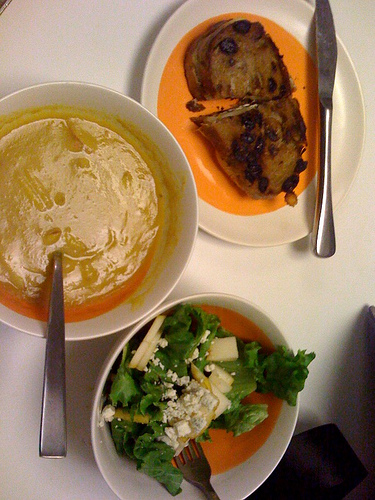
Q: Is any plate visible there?
A: Yes, there is a plate.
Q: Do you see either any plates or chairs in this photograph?
A: Yes, there is a plate.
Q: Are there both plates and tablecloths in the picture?
A: No, there is a plate but no tablecloths.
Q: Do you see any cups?
A: No, there are no cups.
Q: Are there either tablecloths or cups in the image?
A: No, there are no cups or tablecloths.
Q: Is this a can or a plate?
A: This is a plate.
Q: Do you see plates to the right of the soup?
A: Yes, there is a plate to the right of the soup.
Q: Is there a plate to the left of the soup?
A: No, the plate is to the right of the soup.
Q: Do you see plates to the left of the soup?
A: No, the plate is to the right of the soup.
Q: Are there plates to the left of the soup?
A: No, the plate is to the right of the soup.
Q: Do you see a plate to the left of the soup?
A: No, the plate is to the right of the soup.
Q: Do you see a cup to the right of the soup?
A: No, there is a plate to the right of the soup.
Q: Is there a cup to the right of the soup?
A: No, there is a plate to the right of the soup.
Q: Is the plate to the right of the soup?
A: Yes, the plate is to the right of the soup.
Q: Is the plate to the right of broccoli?
A: No, the plate is to the right of the soup.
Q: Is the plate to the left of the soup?
A: No, the plate is to the right of the soup.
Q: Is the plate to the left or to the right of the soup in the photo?
A: The plate is to the right of the soup.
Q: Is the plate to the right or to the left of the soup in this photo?
A: The plate is to the right of the soup.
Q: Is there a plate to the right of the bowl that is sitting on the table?
A: Yes, there is a plate to the right of the bowl.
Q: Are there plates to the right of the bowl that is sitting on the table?
A: Yes, there is a plate to the right of the bowl.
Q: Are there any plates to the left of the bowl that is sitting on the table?
A: No, the plate is to the right of the bowl.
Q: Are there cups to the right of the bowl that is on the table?
A: No, there is a plate to the right of the bowl.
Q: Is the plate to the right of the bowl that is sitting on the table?
A: Yes, the plate is to the right of the bowl.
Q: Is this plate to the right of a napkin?
A: No, the plate is to the right of the bowl.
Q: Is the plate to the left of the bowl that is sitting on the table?
A: No, the plate is to the right of the bowl.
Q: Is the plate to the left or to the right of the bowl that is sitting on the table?
A: The plate is to the right of the bowl.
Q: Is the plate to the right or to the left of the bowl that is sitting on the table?
A: The plate is to the right of the bowl.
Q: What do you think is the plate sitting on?
A: The plate is sitting on the table.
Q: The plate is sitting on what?
A: The plate is sitting on the table.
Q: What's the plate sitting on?
A: The plate is sitting on the table.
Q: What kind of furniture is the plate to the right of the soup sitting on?
A: The plate is sitting on the table.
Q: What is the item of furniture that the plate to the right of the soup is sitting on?
A: The piece of furniture is a table.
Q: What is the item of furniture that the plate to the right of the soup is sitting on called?
A: The piece of furniture is a table.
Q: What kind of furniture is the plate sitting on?
A: The plate is sitting on the table.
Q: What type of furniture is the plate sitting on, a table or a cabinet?
A: The plate is sitting on a table.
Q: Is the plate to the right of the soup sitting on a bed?
A: No, the plate is sitting on the table.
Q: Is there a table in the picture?
A: Yes, there is a table.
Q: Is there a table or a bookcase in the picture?
A: Yes, there is a table.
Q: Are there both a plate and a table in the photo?
A: Yes, there are both a table and a plate.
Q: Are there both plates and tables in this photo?
A: Yes, there are both a table and a plate.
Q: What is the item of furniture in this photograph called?
A: The piece of furniture is a table.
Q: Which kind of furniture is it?
A: The piece of furniture is a table.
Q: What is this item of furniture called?
A: This is a table.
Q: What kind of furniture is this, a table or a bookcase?
A: This is a table.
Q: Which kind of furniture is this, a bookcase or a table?
A: This is a table.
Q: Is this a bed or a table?
A: This is a table.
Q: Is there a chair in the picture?
A: No, there are no chairs.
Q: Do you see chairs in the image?
A: No, there are no chairs.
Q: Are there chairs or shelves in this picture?
A: No, there are no chairs or shelves.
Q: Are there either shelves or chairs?
A: No, there are no chairs or shelves.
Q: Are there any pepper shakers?
A: No, there are no pepper shakers.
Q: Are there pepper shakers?
A: No, there are no pepper shakers.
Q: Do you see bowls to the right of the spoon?
A: Yes, there is a bowl to the right of the spoon.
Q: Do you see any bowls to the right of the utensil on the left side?
A: Yes, there is a bowl to the right of the spoon.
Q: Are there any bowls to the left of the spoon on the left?
A: No, the bowl is to the right of the spoon.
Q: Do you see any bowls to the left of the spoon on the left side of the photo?
A: No, the bowl is to the right of the spoon.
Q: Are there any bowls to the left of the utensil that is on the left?
A: No, the bowl is to the right of the spoon.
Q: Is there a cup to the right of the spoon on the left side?
A: No, there is a bowl to the right of the spoon.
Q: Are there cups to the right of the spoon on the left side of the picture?
A: No, there is a bowl to the right of the spoon.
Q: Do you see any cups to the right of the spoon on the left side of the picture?
A: No, there is a bowl to the right of the spoon.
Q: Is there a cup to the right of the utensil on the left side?
A: No, there is a bowl to the right of the spoon.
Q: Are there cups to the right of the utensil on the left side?
A: No, there is a bowl to the right of the spoon.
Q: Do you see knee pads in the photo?
A: No, there are no knee pads.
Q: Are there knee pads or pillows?
A: No, there are no knee pads or pillows.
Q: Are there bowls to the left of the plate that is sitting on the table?
A: Yes, there is a bowl to the left of the plate.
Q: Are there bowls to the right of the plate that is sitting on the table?
A: No, the bowl is to the left of the plate.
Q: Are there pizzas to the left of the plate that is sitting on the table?
A: No, there is a bowl to the left of the plate.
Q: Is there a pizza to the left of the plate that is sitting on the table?
A: No, there is a bowl to the left of the plate.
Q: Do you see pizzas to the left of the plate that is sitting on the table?
A: No, there is a bowl to the left of the plate.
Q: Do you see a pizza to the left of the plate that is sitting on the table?
A: No, there is a bowl to the left of the plate.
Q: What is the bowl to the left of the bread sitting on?
A: The bowl is sitting on the table.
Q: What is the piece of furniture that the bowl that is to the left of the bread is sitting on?
A: The piece of furniture is a table.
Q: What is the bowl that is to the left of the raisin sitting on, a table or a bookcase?
A: The bowl is sitting on a table.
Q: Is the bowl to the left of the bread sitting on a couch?
A: No, the bowl is sitting on the table.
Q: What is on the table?
A: The bowl is on the table.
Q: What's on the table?
A: The bowl is on the table.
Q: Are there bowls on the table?
A: Yes, there is a bowl on the table.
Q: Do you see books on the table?
A: No, there is a bowl on the table.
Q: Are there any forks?
A: Yes, there is a fork.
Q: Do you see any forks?
A: Yes, there is a fork.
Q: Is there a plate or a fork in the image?
A: Yes, there is a fork.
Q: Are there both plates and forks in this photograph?
A: Yes, there are both a fork and a plate.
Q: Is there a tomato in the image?
A: No, there are no tomatoes.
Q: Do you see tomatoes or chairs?
A: No, there are no tomatoes or chairs.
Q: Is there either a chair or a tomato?
A: No, there are no tomatoes or chairs.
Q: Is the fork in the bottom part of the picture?
A: Yes, the fork is in the bottom of the image.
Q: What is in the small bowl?
A: The fork is in the bowl.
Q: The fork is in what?
A: The fork is in the bowl.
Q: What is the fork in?
A: The fork is in the bowl.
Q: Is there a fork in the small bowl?
A: Yes, there is a fork in the bowl.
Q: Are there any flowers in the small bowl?
A: No, there is a fork in the bowl.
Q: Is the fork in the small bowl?
A: Yes, the fork is in the bowl.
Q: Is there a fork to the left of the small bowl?
A: Yes, there is a fork to the left of the bowl.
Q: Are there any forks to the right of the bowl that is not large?
A: No, the fork is to the left of the bowl.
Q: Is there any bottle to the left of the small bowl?
A: No, there is a fork to the left of the bowl.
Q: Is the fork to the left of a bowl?
A: Yes, the fork is to the left of a bowl.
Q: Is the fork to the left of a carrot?
A: No, the fork is to the left of a bowl.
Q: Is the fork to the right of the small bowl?
A: No, the fork is to the left of the bowl.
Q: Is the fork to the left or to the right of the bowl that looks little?
A: The fork is to the left of the bowl.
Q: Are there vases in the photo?
A: No, there are no vases.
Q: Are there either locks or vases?
A: No, there are no vases or locks.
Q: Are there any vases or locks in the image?
A: No, there are no vases or locks.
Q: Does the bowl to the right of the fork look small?
A: Yes, the bowl is small.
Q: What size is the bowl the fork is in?
A: The bowl is small.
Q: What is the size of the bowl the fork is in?
A: The bowl is small.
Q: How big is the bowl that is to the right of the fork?
A: The bowl is small.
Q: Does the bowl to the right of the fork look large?
A: No, the bowl is small.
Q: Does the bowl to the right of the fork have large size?
A: No, the bowl is small.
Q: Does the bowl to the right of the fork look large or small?
A: The bowl is small.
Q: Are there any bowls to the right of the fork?
A: Yes, there is a bowl to the right of the fork.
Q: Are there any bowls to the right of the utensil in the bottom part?
A: Yes, there is a bowl to the right of the fork.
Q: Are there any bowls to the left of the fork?
A: No, the bowl is to the right of the fork.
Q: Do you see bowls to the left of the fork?
A: No, the bowl is to the right of the fork.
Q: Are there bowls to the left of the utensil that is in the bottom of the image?
A: No, the bowl is to the right of the fork.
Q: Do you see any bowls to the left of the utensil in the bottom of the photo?
A: No, the bowl is to the right of the fork.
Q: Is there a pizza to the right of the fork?
A: No, there is a bowl to the right of the fork.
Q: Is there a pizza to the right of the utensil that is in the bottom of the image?
A: No, there is a bowl to the right of the fork.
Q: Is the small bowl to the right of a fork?
A: Yes, the bowl is to the right of a fork.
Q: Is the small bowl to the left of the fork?
A: No, the bowl is to the right of the fork.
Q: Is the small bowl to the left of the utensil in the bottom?
A: No, the bowl is to the right of the fork.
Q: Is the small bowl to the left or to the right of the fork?
A: The bowl is to the right of the fork.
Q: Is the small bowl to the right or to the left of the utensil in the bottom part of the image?
A: The bowl is to the right of the fork.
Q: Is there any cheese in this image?
A: Yes, there is cheese.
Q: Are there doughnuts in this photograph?
A: No, there are no doughnuts.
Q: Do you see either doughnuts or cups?
A: No, there are no doughnuts or cups.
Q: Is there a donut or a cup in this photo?
A: No, there are no donuts or cups.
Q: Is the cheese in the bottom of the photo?
A: Yes, the cheese is in the bottom of the image.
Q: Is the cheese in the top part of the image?
A: No, the cheese is in the bottom of the image.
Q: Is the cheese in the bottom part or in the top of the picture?
A: The cheese is in the bottom of the image.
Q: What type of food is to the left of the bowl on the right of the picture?
A: The food is cheese.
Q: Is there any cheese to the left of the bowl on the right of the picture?
A: Yes, there is cheese to the left of the bowl.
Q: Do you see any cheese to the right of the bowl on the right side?
A: No, the cheese is to the left of the bowl.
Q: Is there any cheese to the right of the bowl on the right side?
A: No, the cheese is to the left of the bowl.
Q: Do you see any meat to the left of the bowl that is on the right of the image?
A: No, there is cheese to the left of the bowl.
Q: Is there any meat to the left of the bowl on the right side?
A: No, there is cheese to the left of the bowl.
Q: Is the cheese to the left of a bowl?
A: Yes, the cheese is to the left of a bowl.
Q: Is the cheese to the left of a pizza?
A: No, the cheese is to the left of a bowl.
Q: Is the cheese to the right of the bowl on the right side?
A: No, the cheese is to the left of the bowl.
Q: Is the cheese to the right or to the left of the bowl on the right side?
A: The cheese is to the left of the bowl.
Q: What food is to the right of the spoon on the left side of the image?
A: The food is cheese.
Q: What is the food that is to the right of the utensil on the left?
A: The food is cheese.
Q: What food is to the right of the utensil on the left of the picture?
A: The food is cheese.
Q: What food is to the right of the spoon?
A: The food is cheese.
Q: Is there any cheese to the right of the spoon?
A: Yes, there is cheese to the right of the spoon.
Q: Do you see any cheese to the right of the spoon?
A: Yes, there is cheese to the right of the spoon.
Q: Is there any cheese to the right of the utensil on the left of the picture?
A: Yes, there is cheese to the right of the spoon.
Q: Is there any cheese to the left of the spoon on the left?
A: No, the cheese is to the right of the spoon.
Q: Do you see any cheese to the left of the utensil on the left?
A: No, the cheese is to the right of the spoon.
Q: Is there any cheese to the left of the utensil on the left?
A: No, the cheese is to the right of the spoon.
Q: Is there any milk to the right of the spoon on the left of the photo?
A: No, there is cheese to the right of the spoon.